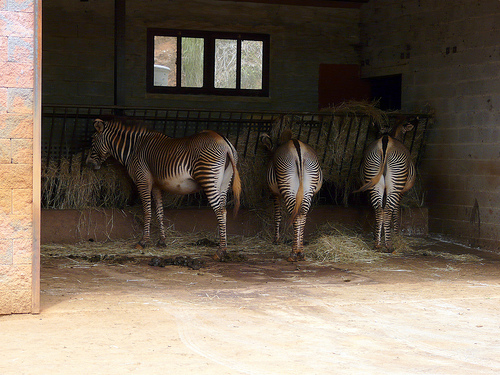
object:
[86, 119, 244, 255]
zebra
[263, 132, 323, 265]
zebra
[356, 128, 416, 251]
zebra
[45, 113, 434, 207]
feeder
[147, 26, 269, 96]
window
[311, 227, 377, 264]
hay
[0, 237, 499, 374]
ground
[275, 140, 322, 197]
hind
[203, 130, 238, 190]
hind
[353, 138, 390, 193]
tail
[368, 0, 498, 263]
wall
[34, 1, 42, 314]
trim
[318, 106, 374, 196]
hay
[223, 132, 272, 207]
hay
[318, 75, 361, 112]
door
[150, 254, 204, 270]
poo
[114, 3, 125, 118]
beam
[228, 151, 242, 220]
tail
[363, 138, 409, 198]
hind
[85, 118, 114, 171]
head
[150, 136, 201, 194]
body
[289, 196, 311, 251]
back legs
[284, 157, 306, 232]
tail